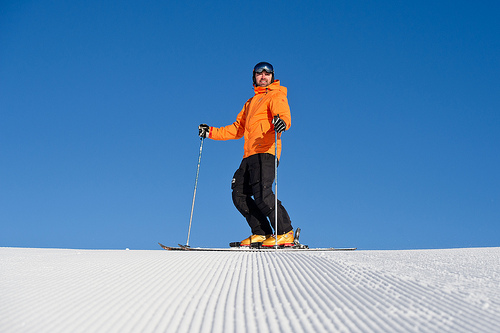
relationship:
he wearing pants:
[198, 62, 294, 247] [232, 153, 298, 230]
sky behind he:
[322, 36, 479, 185] [198, 62, 294, 247]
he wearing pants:
[198, 62, 294, 247] [225, 152, 295, 238]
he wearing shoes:
[198, 62, 294, 247] [239, 228, 294, 245]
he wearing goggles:
[198, 62, 294, 247] [253, 62, 274, 74]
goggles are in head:
[253, 62, 274, 74] [248, 60, 275, 86]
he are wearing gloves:
[198, 62, 294, 247] [195, 119, 212, 138]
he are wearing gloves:
[198, 62, 294, 247] [269, 112, 289, 134]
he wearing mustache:
[198, 62, 294, 247] [253, 68, 273, 79]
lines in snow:
[105, 232, 494, 329] [2, 243, 497, 322]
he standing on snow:
[198, 62, 294, 247] [0, 246, 498, 331]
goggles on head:
[254, 67, 273, 73] [252, 61, 275, 87]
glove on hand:
[268, 114, 285, 132] [270, 115, 287, 133]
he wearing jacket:
[198, 62, 294, 247] [208, 79, 292, 167]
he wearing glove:
[198, 62, 294, 247] [270, 112, 286, 134]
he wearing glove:
[198, 62, 294, 247] [194, 121, 211, 139]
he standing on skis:
[198, 62, 294, 247] [156, 241, 357, 251]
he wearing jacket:
[198, 62, 294, 247] [204, 75, 298, 160]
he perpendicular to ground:
[198, 62, 294, 247] [0, 248, 500, 333]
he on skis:
[198, 62, 294, 247] [159, 237, 356, 252]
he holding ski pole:
[198, 62, 294, 247] [186, 123, 205, 244]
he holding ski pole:
[198, 62, 294, 247] [270, 115, 281, 243]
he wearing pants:
[198, 62, 294, 247] [231, 153, 294, 236]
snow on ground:
[0, 246, 498, 331] [0, 246, 498, 331]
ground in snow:
[0, 248, 500, 333] [10, 246, 450, 330]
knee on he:
[231, 174, 248, 205] [198, 62, 294, 247]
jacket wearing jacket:
[208, 79, 292, 167] [205, 78, 292, 164]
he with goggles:
[198, 62, 294, 247] [254, 67, 273, 73]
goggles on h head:
[254, 67, 273, 73] [251, 60, 275, 88]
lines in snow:
[0, 252, 500, 333] [127, 264, 225, 326]